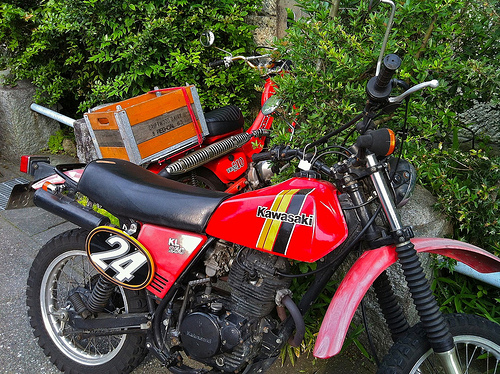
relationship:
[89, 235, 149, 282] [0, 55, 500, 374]
24 on motorcycle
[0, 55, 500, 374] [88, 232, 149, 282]
motorcycle with number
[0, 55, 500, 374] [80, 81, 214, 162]
motorcycle with crate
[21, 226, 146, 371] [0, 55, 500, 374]
wheel on motorcycle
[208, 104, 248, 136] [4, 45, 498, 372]
seat on scooter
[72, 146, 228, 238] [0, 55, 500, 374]
black seat on motorcycle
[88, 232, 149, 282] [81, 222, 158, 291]
number on logo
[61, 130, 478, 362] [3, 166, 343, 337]
motorcycle parked on pavement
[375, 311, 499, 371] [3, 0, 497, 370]
wheel on a motorcycle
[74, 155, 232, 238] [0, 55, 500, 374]
black seat on motorcycle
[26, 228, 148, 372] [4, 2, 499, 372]
tire on bike